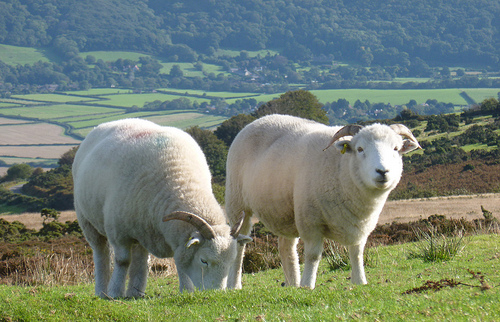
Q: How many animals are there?
A: 2.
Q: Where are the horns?
A: On animal's head.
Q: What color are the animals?
A: White.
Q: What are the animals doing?
A: Grazing.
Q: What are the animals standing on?
A: Grass.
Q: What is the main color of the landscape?
A: Green.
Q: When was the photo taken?
A: Daytime.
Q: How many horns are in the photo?
A: 4.